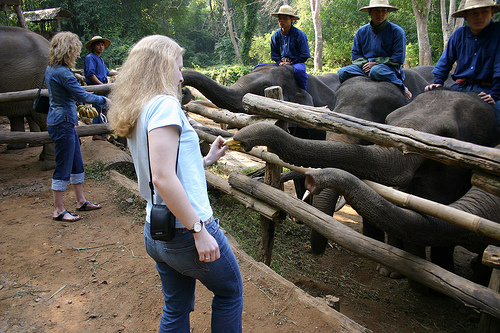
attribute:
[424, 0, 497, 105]
man — young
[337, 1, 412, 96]
man — young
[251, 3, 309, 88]
man — young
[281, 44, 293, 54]
shirt — blue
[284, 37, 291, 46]
hat — brimmed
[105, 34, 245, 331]
woman — blonde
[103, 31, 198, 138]
blonde hair — long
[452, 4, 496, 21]
hat — brimmed